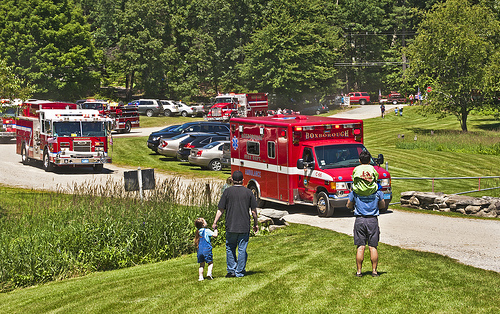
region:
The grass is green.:
[268, 280, 293, 311]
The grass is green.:
[298, 268, 333, 310]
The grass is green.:
[274, 288, 284, 312]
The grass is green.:
[280, 248, 322, 312]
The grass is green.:
[297, 241, 319, 303]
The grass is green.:
[290, 212, 328, 312]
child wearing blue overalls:
[177, 206, 219, 284]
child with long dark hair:
[175, 209, 230, 292]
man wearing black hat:
[178, 164, 273, 282]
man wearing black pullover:
[181, 148, 291, 290]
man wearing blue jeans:
[192, 148, 258, 288]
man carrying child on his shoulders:
[331, 146, 416, 282]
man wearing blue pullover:
[327, 148, 410, 280]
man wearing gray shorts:
[317, 168, 409, 290]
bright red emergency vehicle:
[165, 96, 399, 227]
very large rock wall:
[398, 178, 493, 236]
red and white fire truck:
[16, 99, 113, 171]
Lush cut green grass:
[1, 218, 498, 311]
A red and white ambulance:
[226, 110, 392, 217]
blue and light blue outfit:
[193, 226, 218, 264]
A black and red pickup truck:
[343, 89, 371, 105]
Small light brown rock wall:
[398, 190, 498, 216]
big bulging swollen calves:
[353, 242, 380, 272]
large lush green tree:
[377, 0, 498, 135]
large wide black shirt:
[215, 184, 259, 235]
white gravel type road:
[283, 207, 498, 276]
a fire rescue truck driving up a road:
[217, 110, 390, 216]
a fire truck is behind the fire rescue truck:
[13, 101, 278, 203]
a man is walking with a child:
[187, 167, 261, 286]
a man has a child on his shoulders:
[343, 147, 390, 279]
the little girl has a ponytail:
[185, 212, 225, 282]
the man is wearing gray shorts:
[351, 212, 381, 249]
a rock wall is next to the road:
[401, 187, 499, 223]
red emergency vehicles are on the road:
[3, 90, 391, 217]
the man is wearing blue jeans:
[226, 231, 249, 274]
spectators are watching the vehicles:
[378, 93, 417, 116]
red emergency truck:
[218, 104, 395, 219]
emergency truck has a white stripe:
[211, 101, 401, 218]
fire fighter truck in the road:
[7, 88, 117, 179]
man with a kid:
[181, 161, 268, 285]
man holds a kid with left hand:
[181, 164, 271, 292]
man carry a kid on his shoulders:
[335, 150, 396, 288]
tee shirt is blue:
[342, 194, 392, 219]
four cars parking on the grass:
[140, 107, 230, 165]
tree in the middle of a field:
[390, 1, 491, 138]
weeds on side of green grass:
[15, 164, 175, 272]